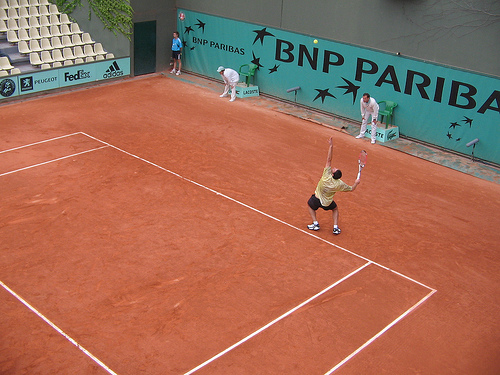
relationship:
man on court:
[299, 120, 370, 241] [109, 85, 316, 225]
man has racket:
[299, 120, 370, 241] [355, 146, 370, 181]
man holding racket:
[299, 120, 370, 241] [355, 146, 370, 181]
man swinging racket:
[299, 120, 370, 241] [355, 146, 370, 181]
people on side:
[170, 30, 392, 139] [169, 82, 357, 164]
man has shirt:
[299, 120, 370, 241] [316, 169, 336, 209]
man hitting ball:
[299, 120, 370, 241] [304, 34, 321, 45]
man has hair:
[299, 120, 370, 241] [334, 170, 342, 184]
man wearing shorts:
[299, 120, 370, 241] [309, 191, 336, 214]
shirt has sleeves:
[316, 169, 336, 209] [320, 162, 334, 176]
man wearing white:
[206, 65, 246, 106] [227, 70, 237, 96]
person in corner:
[167, 27, 186, 85] [157, 5, 214, 92]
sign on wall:
[247, 37, 494, 135] [246, 13, 361, 116]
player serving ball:
[300, 149, 342, 201] [304, 34, 321, 45]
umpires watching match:
[217, 60, 381, 149] [67, 107, 381, 296]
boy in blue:
[162, 27, 183, 67] [172, 41, 177, 49]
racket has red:
[355, 146, 370, 181] [363, 157, 372, 166]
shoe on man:
[310, 219, 322, 233] [299, 120, 370, 241]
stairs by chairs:
[1, 45, 40, 78] [33, 39, 97, 60]